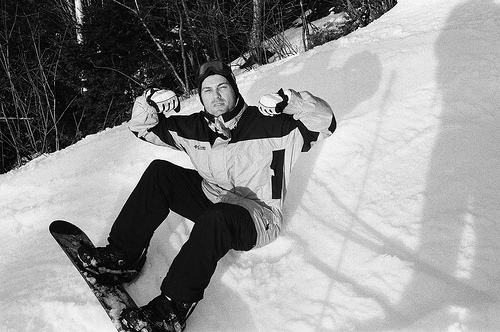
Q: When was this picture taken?
A: Winter.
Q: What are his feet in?
A: A snowboard.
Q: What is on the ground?
A: Snow.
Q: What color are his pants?
A: Black.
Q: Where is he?
A: A mountain.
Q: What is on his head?
A: Goggles.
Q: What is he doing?
A: Posing.